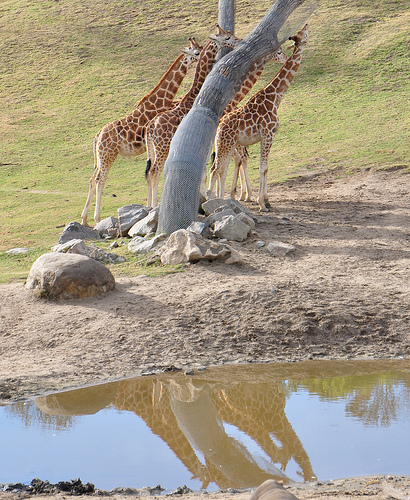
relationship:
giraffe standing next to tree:
[79, 35, 200, 227] [217, 1, 235, 60]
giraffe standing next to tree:
[141, 23, 243, 213] [217, 1, 235, 60]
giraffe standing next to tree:
[199, 46, 288, 201] [155, 0, 303, 235]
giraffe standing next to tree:
[205, 21, 310, 213] [155, 0, 303, 235]